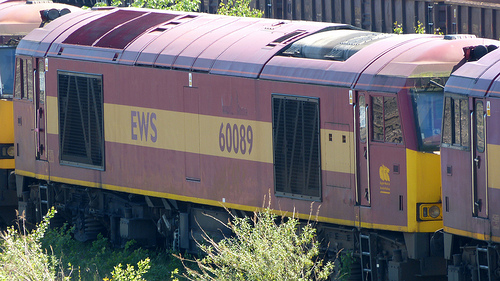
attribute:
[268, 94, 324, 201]
door — open, black, metal, ventilation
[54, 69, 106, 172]
door — ventilation, metal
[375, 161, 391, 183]
logo — yellow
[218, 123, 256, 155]
60089 — identification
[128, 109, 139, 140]
letter — black, purple, e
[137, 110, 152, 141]
letter — w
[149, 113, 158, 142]
letter — s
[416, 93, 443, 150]
windscreen — big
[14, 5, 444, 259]
train — red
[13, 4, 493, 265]
car — yellow, purple, red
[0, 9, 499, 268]
train — abandoned, yellow, red, sitting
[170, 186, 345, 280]
bush — green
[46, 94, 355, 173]
area — tan, yellow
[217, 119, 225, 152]
number — black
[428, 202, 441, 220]
light — round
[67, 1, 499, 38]
train — brown, another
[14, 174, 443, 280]
bottom — black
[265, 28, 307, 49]
vent — exhaust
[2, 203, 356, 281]
grass — green, overgrown